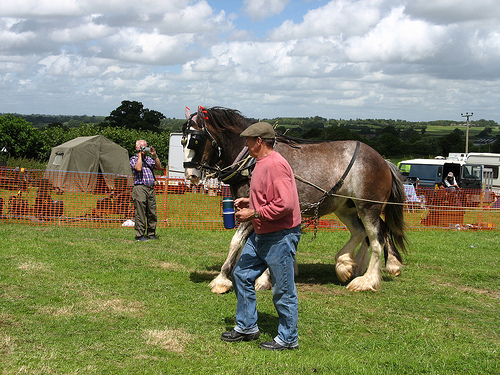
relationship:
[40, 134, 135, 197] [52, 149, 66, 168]
tent with window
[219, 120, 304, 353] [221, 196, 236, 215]
man carrying mug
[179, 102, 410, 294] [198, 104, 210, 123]
horse with ribbons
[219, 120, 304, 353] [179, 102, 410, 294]
man walking beside horse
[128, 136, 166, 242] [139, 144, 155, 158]
man using video camera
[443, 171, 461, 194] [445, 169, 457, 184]
man has head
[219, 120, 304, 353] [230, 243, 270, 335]
man has leg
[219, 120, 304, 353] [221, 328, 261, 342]
man wearing shoe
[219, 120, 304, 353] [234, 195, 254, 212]
man has hand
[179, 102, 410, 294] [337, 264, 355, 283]
horse has hoof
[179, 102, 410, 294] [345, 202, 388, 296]
horse has leg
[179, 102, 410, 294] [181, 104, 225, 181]
horse has head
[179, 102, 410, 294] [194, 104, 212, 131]
horse has ear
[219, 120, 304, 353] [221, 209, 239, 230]
man carrying coffee cup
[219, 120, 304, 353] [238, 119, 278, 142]
man wearing hat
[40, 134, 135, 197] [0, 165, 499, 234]
tent behind fence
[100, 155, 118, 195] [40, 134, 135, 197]
flap open on tent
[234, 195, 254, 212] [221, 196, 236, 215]
hand holding coffee cup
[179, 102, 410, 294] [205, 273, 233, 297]
horse has foot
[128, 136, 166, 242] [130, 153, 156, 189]
man wearing checkered shirt